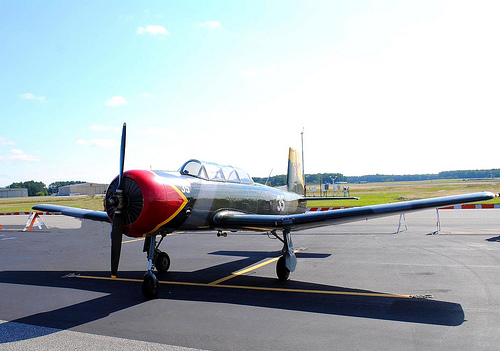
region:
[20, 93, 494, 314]
A vintage airplane with a propeller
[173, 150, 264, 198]
The glass hatch of an airplane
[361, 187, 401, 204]
A green grass field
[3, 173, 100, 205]
Trees growing behind buildings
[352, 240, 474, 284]
A gray asphalt surface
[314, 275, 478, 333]
The shadow of an airplane wing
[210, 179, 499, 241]
A silver metal airplane wing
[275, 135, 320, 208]
A vintage airplane's tail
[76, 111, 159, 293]
The propeller on an airplane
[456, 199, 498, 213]
A red and white striped barrier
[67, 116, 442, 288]
this is a plane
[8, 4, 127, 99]
this is the sky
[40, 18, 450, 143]
this is white and blue skysky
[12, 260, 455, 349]
this is a shadow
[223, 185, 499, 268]
this is a planes wing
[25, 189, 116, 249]
this is a planes wing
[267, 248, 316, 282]
this is a wheel of the plane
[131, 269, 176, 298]
this is a wheel of the plane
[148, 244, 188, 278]
this is a wheel of the plane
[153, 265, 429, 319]
this is a line on the runway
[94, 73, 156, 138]
this is a small cloud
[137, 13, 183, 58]
this is a small cloud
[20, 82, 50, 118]
this is a small cloud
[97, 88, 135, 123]
this is a small cloud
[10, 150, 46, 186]
this is a small cloud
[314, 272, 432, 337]
a shadow of a plane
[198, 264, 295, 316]
a shadow of a plane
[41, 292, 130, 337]
a shadow of a plane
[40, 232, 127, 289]
a shadow of a plane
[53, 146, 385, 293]
small personal propeller airplane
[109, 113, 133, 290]
the propellor of an airplane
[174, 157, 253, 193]
the plane has a clear roof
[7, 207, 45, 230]
traffic barriers on the tarmac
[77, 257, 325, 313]
parking spaces are marked with yellow paint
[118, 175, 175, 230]
the nose of the plane is red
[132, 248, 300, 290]
the plane has three wheels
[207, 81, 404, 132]
the sky is hazy with light clouds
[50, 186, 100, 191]
an airplane hanger is at the end of a field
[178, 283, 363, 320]
the plane is casting a shadow